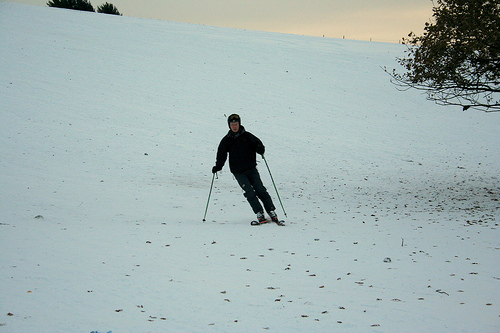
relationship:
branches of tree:
[425, 95, 499, 110] [378, 2, 499, 111]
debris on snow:
[407, 249, 430, 264] [4, 2, 495, 332]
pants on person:
[228, 161, 278, 211] [215, 108, 253, 148]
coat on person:
[215, 125, 266, 174] [182, 109, 357, 243]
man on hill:
[212, 114, 277, 223] [0, 1, 499, 331]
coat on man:
[213, 129, 268, 173] [209, 107, 286, 230]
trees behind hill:
[45, 0, 125, 14] [0, 1, 499, 331]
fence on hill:
[322, 32, 411, 43] [0, 1, 499, 331]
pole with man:
[201, 172, 217, 222] [205, 112, 280, 219]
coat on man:
[215, 125, 266, 174] [209, 107, 286, 230]